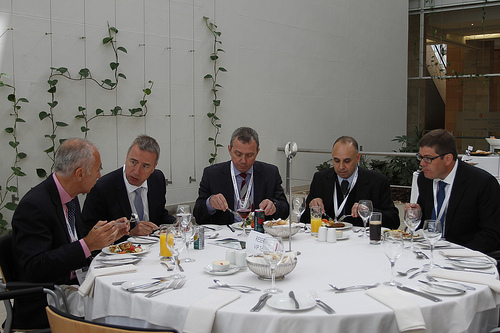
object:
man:
[10, 137, 130, 332]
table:
[76, 219, 500, 332]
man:
[79, 134, 177, 251]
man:
[193, 126, 292, 227]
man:
[299, 136, 399, 230]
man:
[404, 128, 500, 258]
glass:
[309, 203, 323, 237]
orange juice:
[308, 216, 316, 232]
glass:
[157, 226, 176, 258]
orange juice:
[159, 224, 173, 258]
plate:
[263, 289, 318, 312]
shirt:
[50, 172, 94, 268]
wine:
[234, 207, 252, 219]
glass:
[238, 197, 253, 228]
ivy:
[203, 16, 228, 165]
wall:
[3, 1, 405, 243]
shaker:
[316, 224, 328, 244]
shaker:
[327, 224, 339, 242]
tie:
[238, 171, 250, 207]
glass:
[424, 218, 442, 268]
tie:
[433, 180, 447, 230]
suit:
[9, 171, 97, 332]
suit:
[78, 165, 174, 254]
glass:
[175, 203, 193, 230]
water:
[176, 212, 193, 228]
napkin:
[362, 283, 428, 332]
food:
[110, 241, 142, 253]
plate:
[102, 242, 152, 258]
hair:
[415, 128, 457, 159]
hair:
[52, 137, 97, 176]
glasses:
[415, 153, 445, 163]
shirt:
[120, 164, 156, 226]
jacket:
[300, 165, 400, 230]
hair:
[126, 134, 161, 163]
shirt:
[420, 156, 458, 234]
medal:
[331, 166, 358, 223]